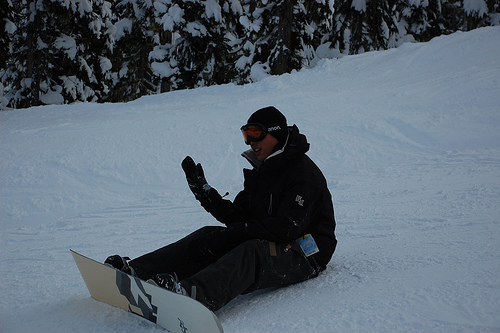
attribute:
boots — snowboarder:
[102, 252, 186, 314]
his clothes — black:
[125, 84, 412, 271]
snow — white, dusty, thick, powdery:
[1, 21, 497, 331]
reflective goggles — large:
[239, 123, 285, 140]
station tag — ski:
[286, 225, 328, 269]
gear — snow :
[110, 107, 340, 309]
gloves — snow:
[179, 153, 214, 203]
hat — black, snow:
[242, 107, 287, 136]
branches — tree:
[3, 0, 498, 107]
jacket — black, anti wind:
[204, 123, 336, 273]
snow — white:
[373, 74, 487, 181]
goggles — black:
[240, 100, 288, 144]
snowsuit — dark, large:
[104, 105, 336, 312]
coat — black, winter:
[203, 122, 339, 278]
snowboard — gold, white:
[17, 47, 499, 331]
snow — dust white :
[36, 112, 139, 209]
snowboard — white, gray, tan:
[67, 251, 217, 332]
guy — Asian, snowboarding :
[103, 101, 338, 313]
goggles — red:
[235, 120, 283, 146]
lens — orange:
[244, 125, 277, 137]